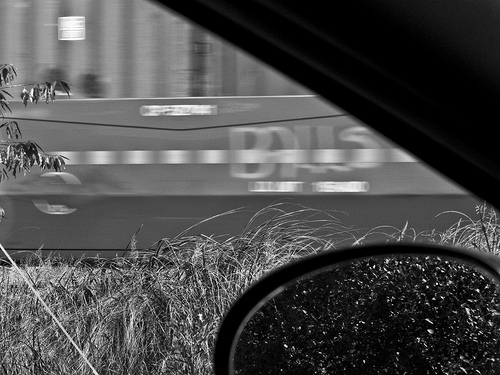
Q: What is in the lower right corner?
A: A mirror.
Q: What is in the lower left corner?
A: Grass.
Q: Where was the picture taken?
A: In a car.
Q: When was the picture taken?
A: Daytime.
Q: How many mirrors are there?
A: One.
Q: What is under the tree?
A: Grass.